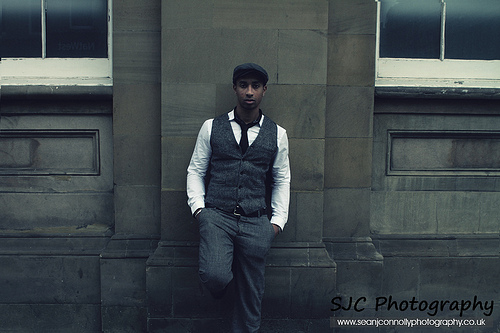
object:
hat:
[231, 62, 270, 87]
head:
[231, 62, 268, 110]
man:
[183, 62, 290, 333]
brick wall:
[160, 1, 332, 243]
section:
[324, 84, 375, 139]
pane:
[443, 0, 499, 61]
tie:
[232, 120, 258, 155]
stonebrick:
[160, 0, 329, 31]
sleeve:
[184, 118, 214, 216]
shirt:
[183, 104, 294, 231]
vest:
[201, 111, 277, 215]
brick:
[324, 85, 376, 139]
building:
[0, 0, 500, 333]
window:
[376, 0, 449, 62]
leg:
[235, 215, 275, 333]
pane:
[44, 0, 109, 58]